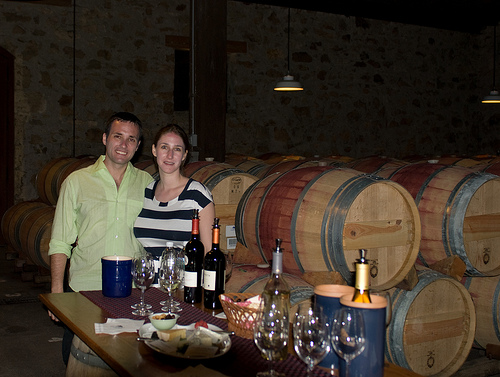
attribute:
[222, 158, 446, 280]
wooden barrels — bunched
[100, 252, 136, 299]
cup — blue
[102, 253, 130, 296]
vase — blue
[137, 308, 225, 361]
plate — white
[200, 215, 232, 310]
wine — red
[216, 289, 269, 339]
basket — wicker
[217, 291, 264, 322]
napkin — red, white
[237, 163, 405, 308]
wooden barrel — underneath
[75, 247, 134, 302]
vase — blue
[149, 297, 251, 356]
flowers — orange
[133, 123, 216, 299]
woman — beside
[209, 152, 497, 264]
barrels — wooden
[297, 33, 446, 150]
stone wall — behind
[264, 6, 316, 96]
light — hanging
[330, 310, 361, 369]
glasses — empty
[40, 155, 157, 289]
shirt — button down, dress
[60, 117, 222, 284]
people — standing